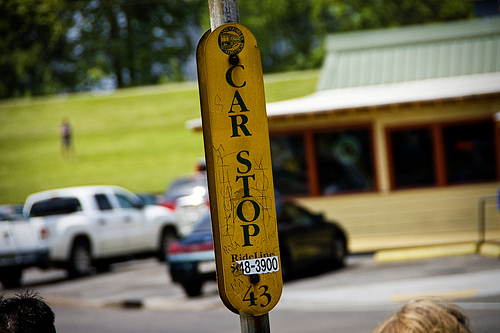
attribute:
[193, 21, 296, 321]
sign — yellow, long, brown, gold, black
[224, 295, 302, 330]
pole — wooden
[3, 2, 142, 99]
trees — green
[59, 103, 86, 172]
person — standing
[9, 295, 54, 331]
hair — brown, pale, blonde, dark, up, black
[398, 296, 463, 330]
hair — blonde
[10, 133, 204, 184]
grass — green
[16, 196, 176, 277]
truck — parked, white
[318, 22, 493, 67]
roof — green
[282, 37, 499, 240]
building — yellow, green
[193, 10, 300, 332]
post — brown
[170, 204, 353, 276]
car — black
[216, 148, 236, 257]
graffiti — scribbles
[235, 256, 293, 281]
sticker — ripped, white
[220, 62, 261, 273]
writing — vertical, black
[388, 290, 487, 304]
line — yellow